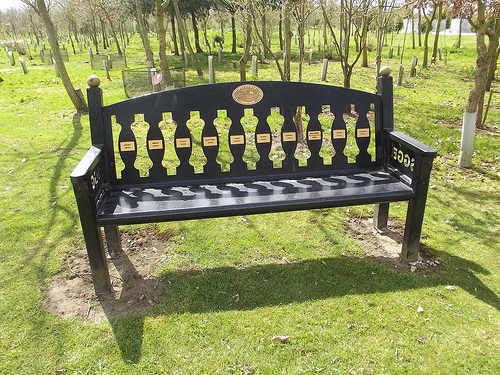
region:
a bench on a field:
[54, 52, 449, 314]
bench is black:
[68, 59, 453, 314]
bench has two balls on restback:
[73, 55, 407, 115]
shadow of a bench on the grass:
[82, 230, 493, 367]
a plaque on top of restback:
[224, 74, 274, 113]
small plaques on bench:
[119, 125, 373, 157]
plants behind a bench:
[27, 0, 484, 80]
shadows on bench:
[105, 170, 401, 216]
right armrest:
[382, 125, 436, 190]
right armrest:
[66, 138, 116, 211]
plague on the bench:
[115, 137, 137, 154]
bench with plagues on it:
[66, 63, 446, 286]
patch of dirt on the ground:
[50, 283, 113, 323]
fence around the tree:
[118, 58, 203, 85]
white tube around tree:
[452, 108, 484, 173]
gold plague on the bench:
[229, 84, 268, 106]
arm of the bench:
[67, 145, 98, 187]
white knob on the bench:
[78, 75, 99, 84]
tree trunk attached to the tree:
[37, 19, 73, 111]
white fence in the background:
[399, 13, 477, 33]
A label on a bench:
[222, 79, 274, 111]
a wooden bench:
[45, 59, 465, 316]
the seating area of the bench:
[100, 164, 413, 222]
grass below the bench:
[197, 240, 370, 331]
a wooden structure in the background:
[391, 6, 482, 44]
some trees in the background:
[142, 9, 358, 51]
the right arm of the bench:
[59, 142, 110, 194]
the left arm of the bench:
[389, 124, 441, 186]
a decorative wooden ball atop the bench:
[72, 67, 115, 101]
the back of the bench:
[99, 70, 387, 182]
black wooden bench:
[52, 73, 441, 253]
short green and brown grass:
[156, 237, 216, 288]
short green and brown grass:
[218, 224, 275, 279]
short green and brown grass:
[198, 294, 271, 360]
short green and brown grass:
[257, 257, 333, 340]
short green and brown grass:
[323, 305, 392, 347]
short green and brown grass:
[388, 315, 450, 363]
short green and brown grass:
[18, 215, 73, 273]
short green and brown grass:
[16, 108, 67, 159]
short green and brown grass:
[411, 78, 441, 126]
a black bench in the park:
[66, 66, 436, 278]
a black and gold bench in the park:
[63, 66, 438, 301]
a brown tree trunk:
[453, 18, 498, 173]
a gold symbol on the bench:
[229, 83, 271, 106]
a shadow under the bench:
[104, 250, 490, 363]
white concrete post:
[200, 56, 220, 87]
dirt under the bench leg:
[34, 246, 160, 328]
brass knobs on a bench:
[85, 76, 100, 88]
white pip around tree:
[460, 111, 477, 179]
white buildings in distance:
[405, 18, 468, 35]